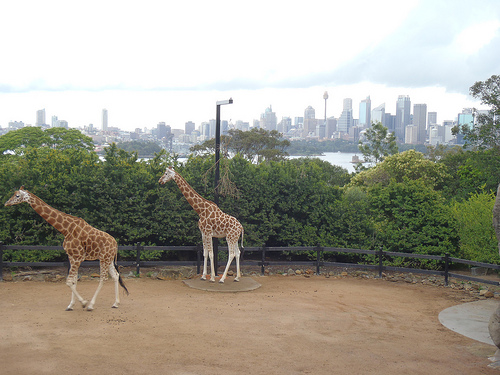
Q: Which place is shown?
A: It is a zoo.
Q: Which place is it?
A: It is a zoo.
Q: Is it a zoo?
A: Yes, it is a zoo.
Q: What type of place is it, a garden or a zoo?
A: It is a zoo.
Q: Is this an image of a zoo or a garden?
A: It is showing a zoo.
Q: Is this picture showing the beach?
A: No, the picture is showing the zoo.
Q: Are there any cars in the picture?
A: No, there are no cars.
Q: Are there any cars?
A: No, there are no cars.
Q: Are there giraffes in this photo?
A: Yes, there is a giraffe.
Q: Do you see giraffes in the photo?
A: Yes, there is a giraffe.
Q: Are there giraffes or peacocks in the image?
A: Yes, there is a giraffe.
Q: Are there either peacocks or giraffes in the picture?
A: Yes, there is a giraffe.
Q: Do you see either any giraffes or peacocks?
A: Yes, there is a giraffe.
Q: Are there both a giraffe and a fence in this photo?
A: Yes, there are both a giraffe and a fence.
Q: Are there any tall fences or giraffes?
A: Yes, there is a tall giraffe.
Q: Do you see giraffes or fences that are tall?
A: Yes, the giraffe is tall.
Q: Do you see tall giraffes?
A: Yes, there is a tall giraffe.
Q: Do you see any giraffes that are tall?
A: Yes, there is a giraffe that is tall.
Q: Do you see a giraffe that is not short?
A: Yes, there is a tall giraffe.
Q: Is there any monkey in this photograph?
A: No, there are no monkeys.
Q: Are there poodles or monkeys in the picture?
A: No, there are no monkeys or poodles.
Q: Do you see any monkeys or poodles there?
A: No, there are no monkeys or poodles.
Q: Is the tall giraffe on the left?
A: Yes, the giraffe is on the left of the image.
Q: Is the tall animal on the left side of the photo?
A: Yes, the giraffe is on the left of the image.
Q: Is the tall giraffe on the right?
A: No, the giraffe is on the left of the image.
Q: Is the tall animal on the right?
A: No, the giraffe is on the left of the image.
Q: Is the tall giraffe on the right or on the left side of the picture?
A: The giraffe is on the left of the image.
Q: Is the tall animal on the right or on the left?
A: The giraffe is on the left of the image.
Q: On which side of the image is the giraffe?
A: The giraffe is on the left of the image.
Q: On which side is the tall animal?
A: The giraffe is on the left of the image.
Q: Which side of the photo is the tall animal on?
A: The giraffe is on the left of the image.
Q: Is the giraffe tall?
A: Yes, the giraffe is tall.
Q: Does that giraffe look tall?
A: Yes, the giraffe is tall.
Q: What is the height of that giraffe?
A: The giraffe is tall.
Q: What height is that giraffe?
A: The giraffe is tall.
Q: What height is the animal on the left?
A: The giraffe is tall.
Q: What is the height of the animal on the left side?
A: The giraffe is tall.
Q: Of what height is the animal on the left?
A: The giraffe is tall.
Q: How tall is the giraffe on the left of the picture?
A: The giraffe is tall.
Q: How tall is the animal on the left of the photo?
A: The giraffe is tall.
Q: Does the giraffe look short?
A: No, the giraffe is tall.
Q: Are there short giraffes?
A: No, there is a giraffe but it is tall.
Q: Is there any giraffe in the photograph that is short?
A: No, there is a giraffe but it is tall.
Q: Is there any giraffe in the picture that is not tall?
A: No, there is a giraffe but it is tall.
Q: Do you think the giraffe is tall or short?
A: The giraffe is tall.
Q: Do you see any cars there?
A: No, there are no cars.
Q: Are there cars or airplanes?
A: No, there are no cars or airplanes.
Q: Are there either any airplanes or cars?
A: No, there are no cars or airplanes.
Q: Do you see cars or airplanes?
A: No, there are no cars or airplanes.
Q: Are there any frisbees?
A: No, there are no frisbees.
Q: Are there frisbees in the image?
A: No, there are no frisbees.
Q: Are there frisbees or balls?
A: No, there are no frisbees or balls.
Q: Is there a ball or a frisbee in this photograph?
A: No, there are no frisbees or balls.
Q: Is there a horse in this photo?
A: No, there are no horses.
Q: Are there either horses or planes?
A: No, there are no horses or planes.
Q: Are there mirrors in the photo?
A: No, there are no mirrors.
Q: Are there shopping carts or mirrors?
A: No, there are no mirrors or shopping carts.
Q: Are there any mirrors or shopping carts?
A: No, there are no mirrors or shopping carts.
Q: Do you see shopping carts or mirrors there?
A: No, there are no mirrors or shopping carts.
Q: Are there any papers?
A: No, there are no papers.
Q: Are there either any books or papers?
A: No, there are no papers or books.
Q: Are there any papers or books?
A: No, there are no papers or books.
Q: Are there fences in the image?
A: Yes, there is a fence.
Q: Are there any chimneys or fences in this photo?
A: Yes, there is a fence.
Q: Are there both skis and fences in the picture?
A: No, there is a fence but no skis.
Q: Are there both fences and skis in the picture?
A: No, there is a fence but no skis.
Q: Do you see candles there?
A: No, there are no candles.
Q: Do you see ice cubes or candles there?
A: No, there are no candles or ice cubes.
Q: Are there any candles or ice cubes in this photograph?
A: No, there are no candles or ice cubes.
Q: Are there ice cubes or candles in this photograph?
A: No, there are no candles or ice cubes.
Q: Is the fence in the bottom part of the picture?
A: Yes, the fence is in the bottom of the image.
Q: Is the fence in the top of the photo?
A: No, the fence is in the bottom of the image.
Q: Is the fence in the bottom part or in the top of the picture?
A: The fence is in the bottom of the image.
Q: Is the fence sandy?
A: Yes, the fence is sandy.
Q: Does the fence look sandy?
A: Yes, the fence is sandy.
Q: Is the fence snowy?
A: No, the fence is sandy.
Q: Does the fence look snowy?
A: No, the fence is sandy.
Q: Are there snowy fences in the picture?
A: No, there is a fence but it is sandy.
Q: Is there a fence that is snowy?
A: No, there is a fence but it is sandy.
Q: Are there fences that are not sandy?
A: No, there is a fence but it is sandy.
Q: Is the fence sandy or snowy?
A: The fence is sandy.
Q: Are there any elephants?
A: No, there are no elephants.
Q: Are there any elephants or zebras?
A: No, there are no elephants or zebras.